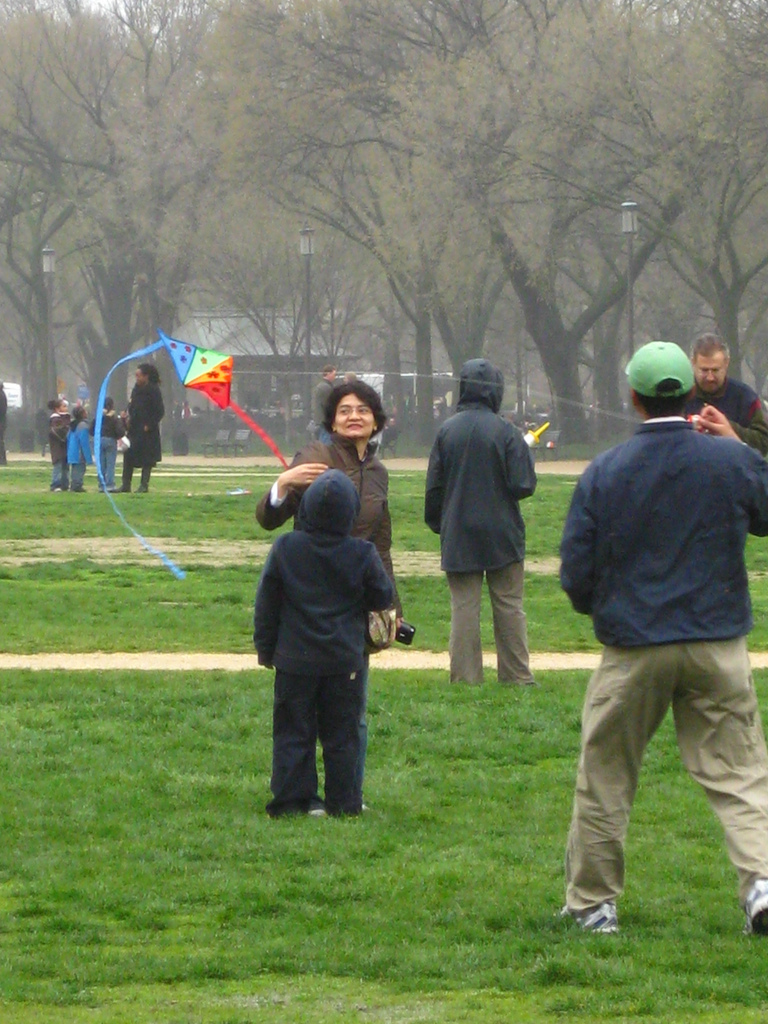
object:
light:
[299, 221, 314, 434]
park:
[0, 0, 768, 1024]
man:
[553, 341, 768, 934]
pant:
[564, 635, 768, 917]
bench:
[202, 429, 251, 458]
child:
[253, 469, 393, 819]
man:
[679, 333, 768, 457]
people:
[254, 333, 768, 936]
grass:
[0, 461, 768, 654]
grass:
[0, 667, 768, 1023]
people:
[253, 381, 404, 821]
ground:
[0, 453, 768, 1024]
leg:
[554, 647, 681, 933]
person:
[553, 340, 768, 938]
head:
[697, 405, 744, 443]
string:
[231, 371, 703, 430]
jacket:
[561, 421, 768, 648]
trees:
[0, 0, 768, 450]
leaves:
[0, 0, 768, 320]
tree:
[203, 0, 768, 444]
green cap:
[625, 341, 696, 398]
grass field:
[0, 461, 766, 1024]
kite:
[94, 328, 289, 578]